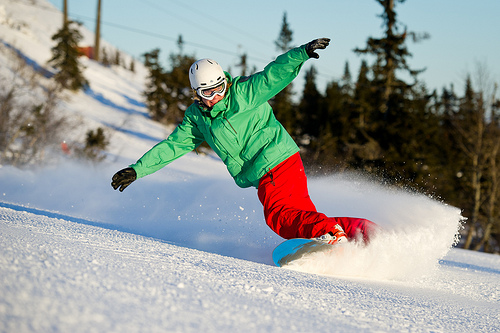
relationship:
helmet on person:
[185, 56, 226, 87] [109, 33, 385, 257]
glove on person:
[111, 165, 138, 191] [109, 33, 385, 257]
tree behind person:
[341, 12, 407, 174] [109, 33, 385, 257]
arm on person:
[132, 113, 200, 174] [109, 33, 385, 257]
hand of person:
[303, 32, 332, 58] [109, 33, 385, 257]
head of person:
[179, 54, 231, 113] [109, 33, 385, 257]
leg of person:
[256, 178, 341, 239] [109, 33, 385, 257]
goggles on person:
[199, 76, 233, 102] [109, 33, 385, 257]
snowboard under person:
[270, 236, 370, 266] [109, 33, 385, 257]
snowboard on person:
[270, 236, 370, 266] [109, 33, 385, 257]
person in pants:
[109, 33, 385, 257] [256, 155, 379, 244]